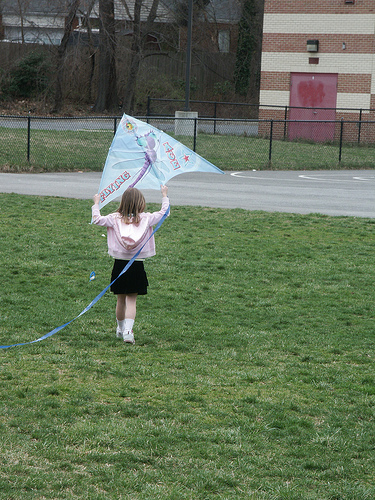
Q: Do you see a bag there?
A: No, there are no bags.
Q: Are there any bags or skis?
A: No, there are no bags or skis.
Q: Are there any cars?
A: No, there are no cars.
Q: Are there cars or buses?
A: No, there are no cars or buses.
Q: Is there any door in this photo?
A: Yes, there is a door.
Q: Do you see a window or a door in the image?
A: Yes, there is a door.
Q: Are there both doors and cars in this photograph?
A: No, there is a door but no cars.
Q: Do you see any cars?
A: No, there are no cars.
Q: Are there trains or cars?
A: No, there are no cars or trains.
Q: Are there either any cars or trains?
A: No, there are no cars or trains.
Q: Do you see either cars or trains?
A: No, there are no cars or trains.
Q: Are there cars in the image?
A: No, there are no cars.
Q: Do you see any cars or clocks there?
A: No, there are no cars or clocks.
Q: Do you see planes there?
A: No, there are no planes.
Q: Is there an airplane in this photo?
A: No, there are no airplanes.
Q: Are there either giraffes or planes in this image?
A: No, there are no planes or giraffes.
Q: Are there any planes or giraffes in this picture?
A: No, there are no planes or giraffes.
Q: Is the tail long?
A: Yes, the tail is long.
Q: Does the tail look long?
A: Yes, the tail is long.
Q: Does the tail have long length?
A: Yes, the tail is long.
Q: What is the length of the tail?
A: The tail is long.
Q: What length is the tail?
A: The tail is long.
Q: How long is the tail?
A: The tail is long.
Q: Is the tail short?
A: No, the tail is long.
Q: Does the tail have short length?
A: No, the tail is long.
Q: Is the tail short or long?
A: The tail is long.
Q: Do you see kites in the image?
A: Yes, there is a kite.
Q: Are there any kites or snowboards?
A: Yes, there is a kite.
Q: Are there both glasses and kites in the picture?
A: No, there is a kite but no glasses.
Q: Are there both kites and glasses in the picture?
A: No, there is a kite but no glasses.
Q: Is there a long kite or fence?
A: Yes, there is a long kite.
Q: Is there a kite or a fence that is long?
A: Yes, the kite is long.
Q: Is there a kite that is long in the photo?
A: Yes, there is a long kite.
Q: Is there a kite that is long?
A: Yes, there is a kite that is long.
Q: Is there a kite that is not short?
A: Yes, there is a long kite.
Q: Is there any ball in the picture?
A: No, there are no balls.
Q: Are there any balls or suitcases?
A: No, there are no balls or suitcases.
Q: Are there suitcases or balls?
A: No, there are no balls or suitcases.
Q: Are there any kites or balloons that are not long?
A: No, there is a kite but it is long.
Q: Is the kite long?
A: Yes, the kite is long.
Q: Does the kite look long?
A: Yes, the kite is long.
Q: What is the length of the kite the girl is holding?
A: The kite is long.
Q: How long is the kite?
A: The kite is long.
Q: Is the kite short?
A: No, the kite is long.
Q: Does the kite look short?
A: No, the kite is long.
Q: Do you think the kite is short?
A: No, the kite is long.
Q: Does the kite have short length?
A: No, the kite is long.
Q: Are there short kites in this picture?
A: No, there is a kite but it is long.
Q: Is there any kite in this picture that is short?
A: No, there is a kite but it is long.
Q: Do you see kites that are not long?
A: No, there is a kite but it is long.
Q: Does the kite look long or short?
A: The kite is long.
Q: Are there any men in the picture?
A: No, there are no men.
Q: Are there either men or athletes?
A: No, there are no men or athletes.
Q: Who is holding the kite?
A: The girl is holding the kite.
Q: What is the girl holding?
A: The girl is holding the kite.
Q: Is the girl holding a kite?
A: Yes, the girl is holding a kite.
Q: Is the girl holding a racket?
A: No, the girl is holding a kite.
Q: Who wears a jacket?
A: The girl wears a jacket.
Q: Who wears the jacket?
A: The girl wears a jacket.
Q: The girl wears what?
A: The girl wears a jacket.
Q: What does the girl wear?
A: The girl wears a jacket.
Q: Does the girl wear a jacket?
A: Yes, the girl wears a jacket.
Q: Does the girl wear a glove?
A: No, the girl wears a jacket.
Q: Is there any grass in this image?
A: Yes, there is grass.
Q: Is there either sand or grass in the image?
A: Yes, there is grass.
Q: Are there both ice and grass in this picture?
A: No, there is grass but no ice.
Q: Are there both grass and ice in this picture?
A: No, there is grass but no ice.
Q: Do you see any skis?
A: No, there are no skis.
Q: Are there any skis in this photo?
A: No, there are no skis.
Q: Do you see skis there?
A: No, there are no skis.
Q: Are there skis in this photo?
A: No, there are no skis.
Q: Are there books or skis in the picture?
A: No, there are no skis or books.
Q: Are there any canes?
A: No, there are no canes.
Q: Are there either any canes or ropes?
A: No, there are no canes or ropes.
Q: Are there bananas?
A: No, there are no bananas.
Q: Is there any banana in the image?
A: No, there are no bananas.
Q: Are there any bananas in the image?
A: No, there are no bananas.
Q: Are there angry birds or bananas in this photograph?
A: No, there are no bananas or angry birds.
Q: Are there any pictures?
A: No, there are no pictures.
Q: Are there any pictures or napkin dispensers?
A: No, there are no pictures or napkin dispensers.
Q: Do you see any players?
A: No, there are no players.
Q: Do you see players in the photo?
A: No, there are no players.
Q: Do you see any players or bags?
A: No, there are no players or bags.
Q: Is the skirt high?
A: Yes, the skirt is high.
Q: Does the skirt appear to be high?
A: Yes, the skirt is high.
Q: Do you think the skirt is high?
A: Yes, the skirt is high.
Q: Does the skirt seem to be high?
A: Yes, the skirt is high.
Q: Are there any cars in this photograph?
A: No, there are no cars.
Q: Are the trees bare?
A: Yes, the trees are bare.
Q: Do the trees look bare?
A: Yes, the trees are bare.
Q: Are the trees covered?
A: No, the trees are bare.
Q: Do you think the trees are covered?
A: No, the trees are bare.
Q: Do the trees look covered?
A: No, the trees are bare.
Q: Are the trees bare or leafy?
A: The trees are bare.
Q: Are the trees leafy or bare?
A: The trees are bare.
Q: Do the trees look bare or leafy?
A: The trees are bare.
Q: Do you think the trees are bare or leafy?
A: The trees are bare.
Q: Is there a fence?
A: Yes, there is a fence.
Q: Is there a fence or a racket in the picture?
A: Yes, there is a fence.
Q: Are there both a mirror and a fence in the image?
A: No, there is a fence but no mirrors.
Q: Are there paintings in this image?
A: No, there are no paintings.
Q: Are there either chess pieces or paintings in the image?
A: No, there are no paintings or chess pieces.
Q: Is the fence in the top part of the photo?
A: Yes, the fence is in the top of the image.